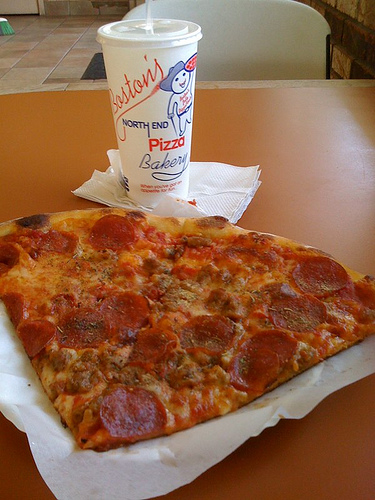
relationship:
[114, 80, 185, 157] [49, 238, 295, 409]
logo on pizza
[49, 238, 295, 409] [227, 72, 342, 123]
pizza on table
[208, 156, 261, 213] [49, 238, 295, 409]
napkin under pizza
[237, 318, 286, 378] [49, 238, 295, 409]
pepperoni on pizza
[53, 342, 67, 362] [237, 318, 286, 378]
herbs on pepperoni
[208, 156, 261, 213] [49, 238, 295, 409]
napkin on pizza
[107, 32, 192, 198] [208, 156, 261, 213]
cup on napkin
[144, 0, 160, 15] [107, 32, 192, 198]
straw in cup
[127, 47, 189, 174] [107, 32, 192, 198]
design on cup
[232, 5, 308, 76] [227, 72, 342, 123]
chair behind table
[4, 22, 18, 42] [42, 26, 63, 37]
broom on floor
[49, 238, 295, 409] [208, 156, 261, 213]
pizza on napkin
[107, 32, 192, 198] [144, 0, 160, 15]
cup has straw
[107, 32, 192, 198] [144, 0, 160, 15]
cup and straw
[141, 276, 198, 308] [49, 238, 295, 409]
cheese on pizza